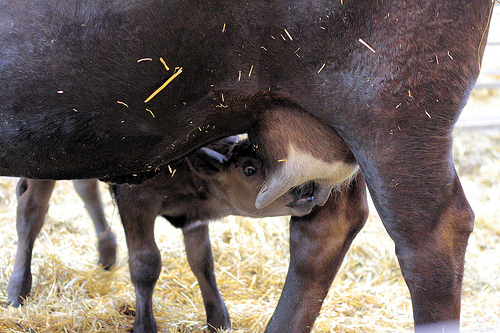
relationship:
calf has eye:
[6, 139, 317, 333] [240, 162, 258, 177]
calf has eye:
[115, 154, 350, 317] [232, 155, 263, 177]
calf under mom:
[6, 139, 317, 333] [1, 0, 494, 333]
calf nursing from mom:
[6, 139, 317, 333] [1, 0, 494, 333]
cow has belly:
[4, 0, 499, 332] [4, 21, 240, 183]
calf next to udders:
[6, 139, 317, 333] [252, 104, 359, 209]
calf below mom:
[6, 139, 317, 333] [1, 0, 496, 331]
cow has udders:
[4, 0, 499, 332] [249, 109, 363, 216]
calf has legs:
[6, 139, 317, 333] [6, 177, 116, 306]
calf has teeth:
[6, 139, 317, 333] [289, 188, 320, 208]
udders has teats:
[243, 92, 357, 212] [250, 172, 332, 208]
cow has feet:
[4, 0, 499, 332] [260, 108, 474, 331]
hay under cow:
[112, 35, 198, 110] [4, 0, 499, 332]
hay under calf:
[112, 35, 198, 110] [6, 139, 317, 333]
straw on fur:
[135, 65, 203, 113] [73, 45, 121, 85]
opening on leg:
[14, 179, 34, 199] [4, 177, 56, 309]